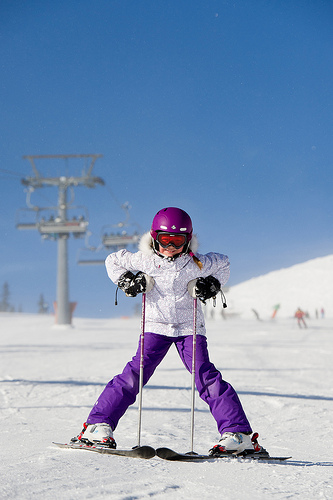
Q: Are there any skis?
A: Yes, there are skis.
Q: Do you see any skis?
A: Yes, there are skis.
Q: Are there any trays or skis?
A: Yes, there are skis.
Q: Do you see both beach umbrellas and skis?
A: No, there are skis but no beach umbrellas.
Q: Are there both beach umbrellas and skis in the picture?
A: No, there are skis but no beach umbrellas.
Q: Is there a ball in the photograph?
A: No, there are no balls.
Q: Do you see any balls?
A: No, there are no balls.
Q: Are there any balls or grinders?
A: No, there are no balls or grinders.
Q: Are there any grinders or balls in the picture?
A: No, there are no balls or grinders.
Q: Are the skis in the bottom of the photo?
A: Yes, the skis are in the bottom of the image.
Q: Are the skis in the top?
A: No, the skis are in the bottom of the image.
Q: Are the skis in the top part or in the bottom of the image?
A: The skis are in the bottom of the image.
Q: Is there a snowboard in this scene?
A: No, there are no snowboards.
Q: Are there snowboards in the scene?
A: No, there are no snowboards.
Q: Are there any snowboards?
A: No, there are no snowboards.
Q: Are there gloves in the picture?
A: Yes, there are gloves.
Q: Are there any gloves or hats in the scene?
A: Yes, there are gloves.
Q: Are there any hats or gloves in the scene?
A: Yes, there are gloves.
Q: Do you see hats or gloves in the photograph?
A: Yes, there are gloves.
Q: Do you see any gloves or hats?
A: Yes, there are gloves.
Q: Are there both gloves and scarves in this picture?
A: No, there are gloves but no scarves.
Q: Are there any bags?
A: No, there are no bags.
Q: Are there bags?
A: No, there are no bags.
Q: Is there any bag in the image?
A: No, there are no bags.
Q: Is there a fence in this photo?
A: No, there are no fences.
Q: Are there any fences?
A: No, there are no fences.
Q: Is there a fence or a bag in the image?
A: No, there are no fences or bags.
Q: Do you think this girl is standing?
A: Yes, the girl is standing.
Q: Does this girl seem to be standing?
A: Yes, the girl is standing.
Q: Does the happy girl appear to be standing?
A: Yes, the girl is standing.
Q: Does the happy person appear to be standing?
A: Yes, the girl is standing.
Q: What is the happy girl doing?
A: The girl is standing.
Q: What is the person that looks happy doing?
A: The girl is standing.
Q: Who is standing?
A: The girl is standing.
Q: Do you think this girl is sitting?
A: No, the girl is standing.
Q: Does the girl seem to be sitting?
A: No, the girl is standing.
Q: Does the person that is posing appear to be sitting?
A: No, the girl is standing.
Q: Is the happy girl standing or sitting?
A: The girl is standing.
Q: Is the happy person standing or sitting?
A: The girl is standing.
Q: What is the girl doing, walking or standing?
A: The girl is standing.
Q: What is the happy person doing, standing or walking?
A: The girl is standing.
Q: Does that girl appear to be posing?
A: Yes, the girl is posing.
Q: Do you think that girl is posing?
A: Yes, the girl is posing.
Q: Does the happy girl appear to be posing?
A: Yes, the girl is posing.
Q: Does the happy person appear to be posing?
A: Yes, the girl is posing.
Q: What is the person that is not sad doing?
A: The girl is posing.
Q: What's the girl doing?
A: The girl is posing.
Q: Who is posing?
A: The girl is posing.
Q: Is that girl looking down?
A: No, the girl is posing.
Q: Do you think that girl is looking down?
A: No, the girl is posing.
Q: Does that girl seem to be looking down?
A: No, the girl is posing.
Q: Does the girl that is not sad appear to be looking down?
A: No, the girl is posing.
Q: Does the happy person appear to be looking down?
A: No, the girl is posing.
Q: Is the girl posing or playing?
A: The girl is posing.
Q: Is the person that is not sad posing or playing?
A: The girl is posing.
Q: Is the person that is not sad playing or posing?
A: The girl is posing.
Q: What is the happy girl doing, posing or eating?
A: The girl is posing.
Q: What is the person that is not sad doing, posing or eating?
A: The girl is posing.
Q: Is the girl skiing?
A: Yes, the girl is skiing.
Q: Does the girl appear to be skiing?
A: Yes, the girl is skiing.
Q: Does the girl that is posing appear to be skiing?
A: Yes, the girl is skiing.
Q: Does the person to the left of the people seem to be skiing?
A: Yes, the girl is skiing.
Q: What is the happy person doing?
A: The girl is skiing.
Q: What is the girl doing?
A: The girl is skiing.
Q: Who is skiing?
A: The girl is skiing.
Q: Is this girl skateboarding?
A: No, the girl is skiing.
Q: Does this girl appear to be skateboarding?
A: No, the girl is skiing.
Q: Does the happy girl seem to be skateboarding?
A: No, the girl is skiing.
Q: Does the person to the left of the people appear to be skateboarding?
A: No, the girl is skiing.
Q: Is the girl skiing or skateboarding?
A: The girl is skiing.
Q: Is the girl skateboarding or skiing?
A: The girl is skiing.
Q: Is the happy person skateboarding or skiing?
A: The girl is skiing.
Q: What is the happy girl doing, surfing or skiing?
A: The girl is skiing.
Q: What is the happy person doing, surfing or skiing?
A: The girl is skiing.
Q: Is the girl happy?
A: Yes, the girl is happy.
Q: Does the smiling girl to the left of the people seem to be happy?
A: Yes, the girl is happy.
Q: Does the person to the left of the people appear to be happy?
A: Yes, the girl is happy.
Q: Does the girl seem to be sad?
A: No, the girl is happy.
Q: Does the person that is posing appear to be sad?
A: No, the girl is happy.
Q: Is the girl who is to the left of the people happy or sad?
A: The girl is happy.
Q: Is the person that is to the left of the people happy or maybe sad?
A: The girl is happy.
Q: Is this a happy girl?
A: Yes, this is a happy girl.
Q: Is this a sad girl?
A: No, this is a happy girl.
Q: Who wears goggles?
A: The girl wears goggles.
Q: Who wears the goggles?
A: The girl wears goggles.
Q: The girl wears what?
A: The girl wears goggles.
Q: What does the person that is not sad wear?
A: The girl wears goggles.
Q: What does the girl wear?
A: The girl wears goggles.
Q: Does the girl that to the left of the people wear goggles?
A: Yes, the girl wears goggles.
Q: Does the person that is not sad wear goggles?
A: Yes, the girl wears goggles.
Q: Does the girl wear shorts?
A: No, the girl wears goggles.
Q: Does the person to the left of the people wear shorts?
A: No, the girl wears goggles.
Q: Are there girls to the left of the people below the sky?
A: Yes, there is a girl to the left of the people.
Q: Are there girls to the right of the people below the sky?
A: No, the girl is to the left of the people.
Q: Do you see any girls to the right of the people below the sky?
A: No, the girl is to the left of the people.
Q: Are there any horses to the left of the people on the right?
A: No, there is a girl to the left of the people.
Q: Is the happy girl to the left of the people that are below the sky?
A: Yes, the girl is to the left of the people.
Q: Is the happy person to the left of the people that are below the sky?
A: Yes, the girl is to the left of the people.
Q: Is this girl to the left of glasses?
A: No, the girl is to the left of the people.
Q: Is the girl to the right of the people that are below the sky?
A: No, the girl is to the left of the people.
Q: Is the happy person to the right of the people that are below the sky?
A: No, the girl is to the left of the people.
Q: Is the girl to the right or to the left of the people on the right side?
A: The girl is to the left of the people.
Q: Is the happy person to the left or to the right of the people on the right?
A: The girl is to the left of the people.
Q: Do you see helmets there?
A: Yes, there is a helmet.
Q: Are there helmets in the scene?
A: Yes, there is a helmet.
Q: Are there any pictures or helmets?
A: Yes, there is a helmet.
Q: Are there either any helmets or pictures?
A: Yes, there is a helmet.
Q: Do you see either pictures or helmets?
A: Yes, there is a helmet.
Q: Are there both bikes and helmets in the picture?
A: No, there is a helmet but no bikes.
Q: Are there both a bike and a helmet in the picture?
A: No, there is a helmet but no bikes.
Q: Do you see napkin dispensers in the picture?
A: No, there are no napkin dispensers.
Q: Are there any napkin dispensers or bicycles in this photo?
A: No, there are no napkin dispensers or bicycles.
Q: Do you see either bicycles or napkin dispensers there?
A: No, there are no napkin dispensers or bicycles.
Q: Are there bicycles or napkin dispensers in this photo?
A: No, there are no napkin dispensers or bicycles.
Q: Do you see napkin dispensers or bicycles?
A: No, there are no napkin dispensers or bicycles.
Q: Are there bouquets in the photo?
A: No, there are no bouquets.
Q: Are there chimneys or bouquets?
A: No, there are no bouquets or chimneys.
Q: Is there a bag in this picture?
A: No, there are no bags.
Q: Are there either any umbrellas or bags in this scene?
A: No, there are no bags or umbrellas.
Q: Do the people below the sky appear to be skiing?
A: Yes, the people are skiing.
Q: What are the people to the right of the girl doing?
A: The people are skiing.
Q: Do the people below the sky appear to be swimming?
A: No, the people are skiing.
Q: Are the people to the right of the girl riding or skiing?
A: The people are skiing.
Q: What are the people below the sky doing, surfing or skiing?
A: The people are skiing.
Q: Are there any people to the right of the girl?
A: Yes, there are people to the right of the girl.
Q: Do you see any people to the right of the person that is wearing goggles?
A: Yes, there are people to the right of the girl.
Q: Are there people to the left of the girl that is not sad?
A: No, the people are to the right of the girl.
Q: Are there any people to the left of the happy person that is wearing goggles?
A: No, the people are to the right of the girl.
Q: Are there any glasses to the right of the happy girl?
A: No, there are people to the right of the girl.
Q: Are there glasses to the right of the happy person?
A: No, there are people to the right of the girl.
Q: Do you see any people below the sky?
A: Yes, there are people below the sky.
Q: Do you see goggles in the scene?
A: Yes, there are goggles.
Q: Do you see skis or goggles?
A: Yes, there are goggles.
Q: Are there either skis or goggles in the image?
A: Yes, there are goggles.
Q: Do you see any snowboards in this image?
A: No, there are no snowboards.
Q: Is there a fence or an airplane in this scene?
A: No, there are no fences or airplanes.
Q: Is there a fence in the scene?
A: No, there are no fences.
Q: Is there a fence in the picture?
A: No, there are no fences.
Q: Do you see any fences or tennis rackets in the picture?
A: No, there are no fences or tennis rackets.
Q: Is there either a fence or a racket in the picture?
A: No, there are no fences or rackets.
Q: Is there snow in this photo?
A: Yes, there is snow.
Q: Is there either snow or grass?
A: Yes, there is snow.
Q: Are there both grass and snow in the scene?
A: No, there is snow but no grass.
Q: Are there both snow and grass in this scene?
A: No, there is snow but no grass.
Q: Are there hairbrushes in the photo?
A: No, there are no hairbrushes.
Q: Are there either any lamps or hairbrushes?
A: No, there are no hairbrushes or lamps.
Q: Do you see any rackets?
A: No, there are no rackets.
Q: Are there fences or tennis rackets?
A: No, there are no tennis rackets or fences.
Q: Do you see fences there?
A: No, there are no fences.